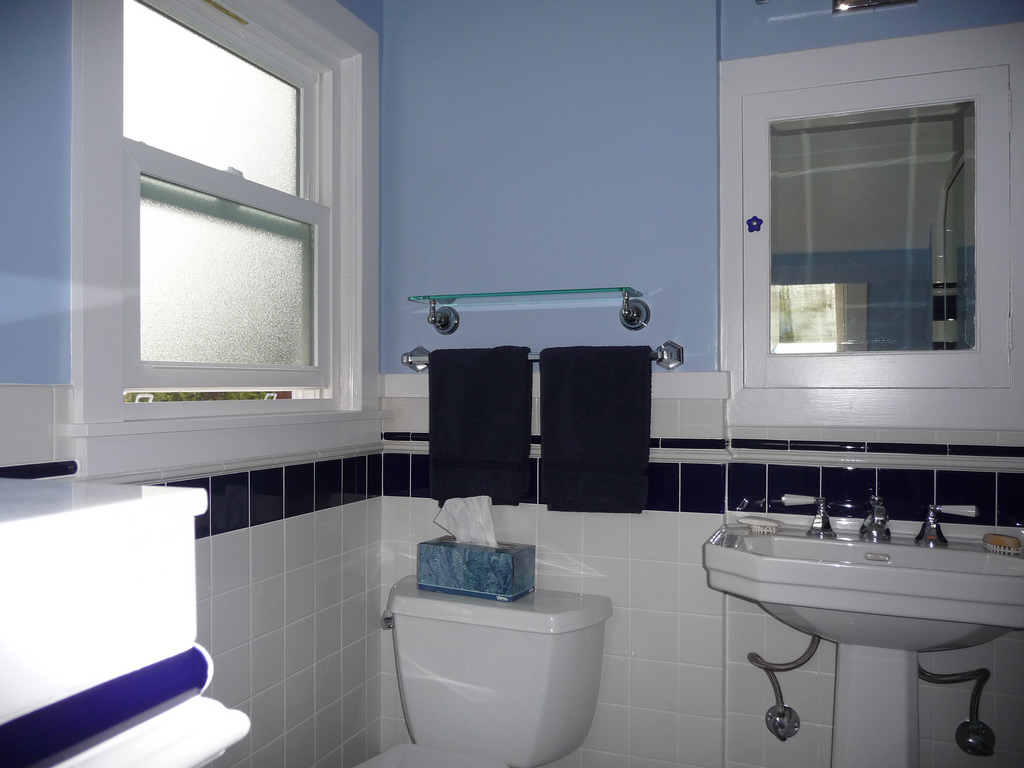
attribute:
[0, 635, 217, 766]
bar — blue, plastic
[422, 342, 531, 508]
towel — large, black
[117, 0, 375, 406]
window — slightly open